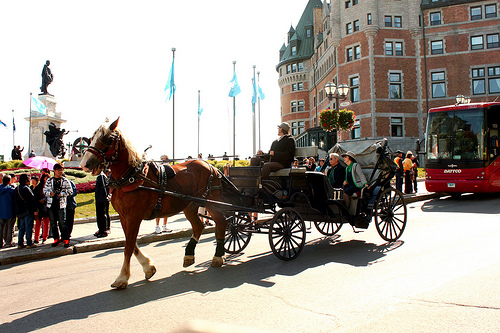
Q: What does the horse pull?
A: A carriage.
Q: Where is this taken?
A: A city street.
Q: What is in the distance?
A: Brick building.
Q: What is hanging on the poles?
A: Flags.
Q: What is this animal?
A: Horse.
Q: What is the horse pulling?
A: Carriage.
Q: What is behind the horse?
A: Bus.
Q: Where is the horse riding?
A: Street.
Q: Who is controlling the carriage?
A: Driver.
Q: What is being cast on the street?
A: Shadow.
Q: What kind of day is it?
A: Sunny.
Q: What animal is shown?
A: HOrse.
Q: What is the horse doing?
A: Pulling the cart.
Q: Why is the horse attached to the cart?
A: To pull it.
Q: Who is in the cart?
A: Tourists.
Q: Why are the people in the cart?
A: Transportation.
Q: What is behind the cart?
A: A bus.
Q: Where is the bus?
A: On the road.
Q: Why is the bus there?
A: Transportation.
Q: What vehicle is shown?
A: The bus.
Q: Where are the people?
A: On the sidewalk.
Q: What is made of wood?
A: The wheels.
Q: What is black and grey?
A: The carriage.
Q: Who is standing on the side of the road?
A: A group of people.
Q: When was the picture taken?
A: Daytime.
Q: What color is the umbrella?
A: Pink.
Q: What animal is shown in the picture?
A: Horse.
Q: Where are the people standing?
A: Sidewalk.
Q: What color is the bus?
A: Red.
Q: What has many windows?
A: Building.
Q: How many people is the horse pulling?
A: Three.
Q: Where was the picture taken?
A: At a parade.